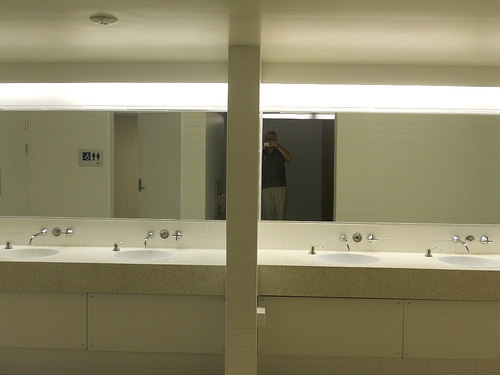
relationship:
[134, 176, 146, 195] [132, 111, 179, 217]
handle for door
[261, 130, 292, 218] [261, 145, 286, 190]
man wearing black shirt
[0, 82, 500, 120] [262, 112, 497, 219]
light above mirror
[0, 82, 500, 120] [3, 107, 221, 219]
light above mirror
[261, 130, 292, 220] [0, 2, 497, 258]
man in mirror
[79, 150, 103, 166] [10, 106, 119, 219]
bathroom sign on wall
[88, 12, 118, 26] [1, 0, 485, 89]
sprinkler in ceiling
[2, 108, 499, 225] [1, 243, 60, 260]
mirror above sinks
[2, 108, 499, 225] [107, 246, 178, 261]
mirror above sinks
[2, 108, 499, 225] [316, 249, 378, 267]
mirror above sinks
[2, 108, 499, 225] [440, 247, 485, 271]
mirror above sinks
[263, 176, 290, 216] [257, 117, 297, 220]
pants on person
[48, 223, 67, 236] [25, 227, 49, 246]
knobs on faucet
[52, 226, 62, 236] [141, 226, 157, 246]
knobs on faucet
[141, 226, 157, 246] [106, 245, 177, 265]
faucet on sink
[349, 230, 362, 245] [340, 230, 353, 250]
knobs on facuet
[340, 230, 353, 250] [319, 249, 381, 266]
facuet on sink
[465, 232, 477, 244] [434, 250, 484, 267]
knobs on sink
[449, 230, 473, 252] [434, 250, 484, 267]
faucet on sink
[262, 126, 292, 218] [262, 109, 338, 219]
reflection in mirror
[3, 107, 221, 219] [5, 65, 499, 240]
mirror on wall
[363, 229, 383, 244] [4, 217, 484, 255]
tap on wall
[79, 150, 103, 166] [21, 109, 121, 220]
bathroom sign on wall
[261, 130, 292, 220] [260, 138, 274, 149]
man holding phone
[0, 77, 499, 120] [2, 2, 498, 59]
light on ceiling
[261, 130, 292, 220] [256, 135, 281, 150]
man taking photo with phone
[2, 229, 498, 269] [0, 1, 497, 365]
sinks in restroom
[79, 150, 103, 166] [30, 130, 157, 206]
bathroom sign on reflection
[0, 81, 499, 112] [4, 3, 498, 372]
lighting in bathroom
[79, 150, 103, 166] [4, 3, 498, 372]
bathroom sign in bathroom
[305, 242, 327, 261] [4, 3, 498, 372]
dispenser in bathroom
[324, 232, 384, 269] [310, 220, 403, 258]
sink on wall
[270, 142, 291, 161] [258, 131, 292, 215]
left arm of man